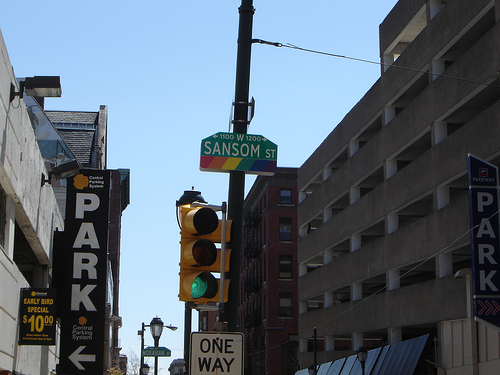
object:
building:
[180, 0, 494, 368]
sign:
[190, 333, 244, 375]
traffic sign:
[172, 196, 230, 309]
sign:
[468, 157, 498, 319]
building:
[0, 41, 121, 372]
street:
[2, 7, 493, 373]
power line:
[246, 28, 387, 68]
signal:
[181, 270, 221, 309]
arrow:
[63, 337, 96, 373]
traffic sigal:
[171, 188, 231, 317]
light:
[188, 276, 218, 305]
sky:
[0, 3, 399, 371]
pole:
[153, 339, 160, 374]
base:
[134, 339, 172, 362]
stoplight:
[175, 201, 232, 311]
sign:
[65, 167, 103, 373]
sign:
[18, 285, 58, 346]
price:
[21, 310, 53, 330]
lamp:
[148, 319, 173, 373]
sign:
[137, 345, 175, 358]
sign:
[200, 132, 278, 174]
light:
[16, 75, 64, 102]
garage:
[0, 29, 68, 347]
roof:
[47, 109, 92, 131]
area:
[0, 160, 22, 367]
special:
[23, 297, 55, 342]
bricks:
[272, 247, 275, 248]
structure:
[294, 157, 462, 312]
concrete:
[361, 192, 398, 216]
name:
[200, 138, 273, 159]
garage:
[295, 51, 500, 361]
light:
[192, 208, 219, 231]